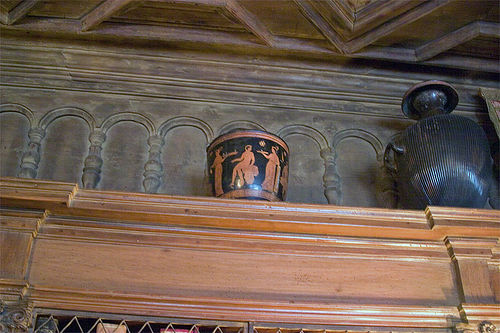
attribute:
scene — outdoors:
[15, 11, 499, 316]